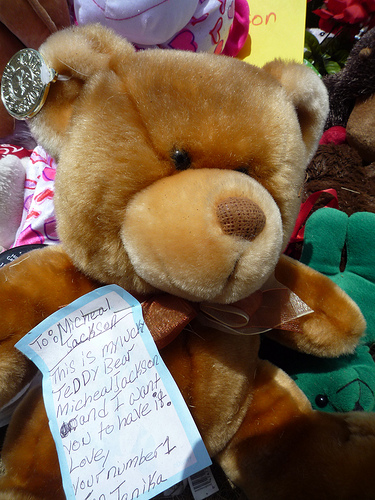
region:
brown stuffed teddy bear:
[13, 18, 332, 498]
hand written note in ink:
[3, 309, 200, 496]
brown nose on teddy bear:
[211, 200, 268, 246]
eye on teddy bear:
[158, 135, 193, 174]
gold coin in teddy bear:
[0, 54, 72, 112]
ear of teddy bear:
[21, 24, 98, 140]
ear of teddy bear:
[260, 64, 331, 176]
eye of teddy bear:
[234, 160, 255, 175]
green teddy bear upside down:
[301, 207, 374, 418]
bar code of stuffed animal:
[186, 468, 219, 497]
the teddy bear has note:
[15, 227, 170, 486]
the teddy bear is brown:
[21, 51, 327, 478]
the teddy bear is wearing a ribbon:
[87, 262, 248, 338]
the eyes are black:
[148, 113, 300, 216]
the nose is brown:
[201, 145, 280, 241]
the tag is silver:
[4, 40, 81, 164]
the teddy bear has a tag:
[4, 45, 103, 179]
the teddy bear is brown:
[138, 114, 284, 285]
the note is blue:
[38, 317, 171, 495]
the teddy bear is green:
[292, 205, 356, 434]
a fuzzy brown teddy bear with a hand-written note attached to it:
[8, 69, 351, 498]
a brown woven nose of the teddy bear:
[211, 192, 270, 242]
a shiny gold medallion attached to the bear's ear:
[0, 43, 57, 129]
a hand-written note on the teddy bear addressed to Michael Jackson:
[15, 288, 230, 498]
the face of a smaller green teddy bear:
[283, 357, 374, 415]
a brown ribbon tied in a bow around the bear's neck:
[211, 286, 318, 336]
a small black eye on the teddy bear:
[165, 147, 196, 171]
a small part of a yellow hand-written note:
[250, 2, 316, 70]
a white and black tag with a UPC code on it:
[187, 466, 222, 496]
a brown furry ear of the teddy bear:
[260, 57, 335, 153]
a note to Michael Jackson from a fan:
[17, 290, 195, 498]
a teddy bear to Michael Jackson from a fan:
[42, 39, 339, 303]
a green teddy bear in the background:
[288, 203, 371, 413]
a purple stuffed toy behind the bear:
[1, 2, 246, 259]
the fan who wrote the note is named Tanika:
[107, 471, 166, 498]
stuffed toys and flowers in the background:
[284, 0, 374, 210]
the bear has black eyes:
[142, 119, 296, 307]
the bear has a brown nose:
[175, 168, 293, 248]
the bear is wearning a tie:
[127, 273, 316, 373]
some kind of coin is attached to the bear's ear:
[0, 17, 352, 236]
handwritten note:
[38, 272, 198, 492]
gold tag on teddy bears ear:
[6, 42, 74, 120]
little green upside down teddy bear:
[281, 201, 373, 412]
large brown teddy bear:
[11, 69, 304, 488]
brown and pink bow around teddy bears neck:
[159, 271, 310, 345]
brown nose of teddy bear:
[210, 193, 271, 236]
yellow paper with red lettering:
[216, 5, 305, 67]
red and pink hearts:
[173, 9, 232, 51]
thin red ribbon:
[274, 183, 337, 249]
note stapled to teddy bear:
[63, 287, 133, 338]